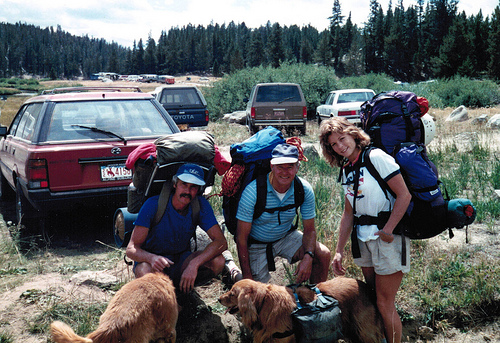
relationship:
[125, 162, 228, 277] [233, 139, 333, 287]
backpacker next to backpacker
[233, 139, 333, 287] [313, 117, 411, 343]
backpacker next to lady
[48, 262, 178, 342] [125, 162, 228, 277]
dog next to backpacker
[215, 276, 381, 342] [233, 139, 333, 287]
dog next to backpacker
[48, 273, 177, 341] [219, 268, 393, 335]
dog near dog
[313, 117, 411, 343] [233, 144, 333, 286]
lady near backpacker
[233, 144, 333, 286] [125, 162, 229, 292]
backpacker near backpacker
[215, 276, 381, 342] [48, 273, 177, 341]
dog near dog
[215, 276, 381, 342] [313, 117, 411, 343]
dog in front of lady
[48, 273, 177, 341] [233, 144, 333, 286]
dog in front of backpacker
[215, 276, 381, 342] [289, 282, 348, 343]
dog carrying bag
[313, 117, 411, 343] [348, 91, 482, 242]
lady carrying backpack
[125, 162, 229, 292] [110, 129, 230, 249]
backpacker carrying camping gear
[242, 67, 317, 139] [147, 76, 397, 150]
van between vehicles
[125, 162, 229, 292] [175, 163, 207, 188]
backpacker wearing cap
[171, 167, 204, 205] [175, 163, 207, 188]
head wearing cap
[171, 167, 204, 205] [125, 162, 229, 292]
head belonging to backpacker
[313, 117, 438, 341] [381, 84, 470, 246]
lady carrying backpack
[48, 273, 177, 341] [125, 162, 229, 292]
dog in front of backpacker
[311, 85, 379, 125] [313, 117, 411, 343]
car behind a lady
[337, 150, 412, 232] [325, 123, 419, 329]
shirt on a woman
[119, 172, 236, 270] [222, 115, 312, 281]
shirt on a man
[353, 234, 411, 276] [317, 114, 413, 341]
shorts on a woman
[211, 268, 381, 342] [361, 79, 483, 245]
dog with backpack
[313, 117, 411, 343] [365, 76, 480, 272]
lady with a hiking backpack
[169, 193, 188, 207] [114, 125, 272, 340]
moustache on a man